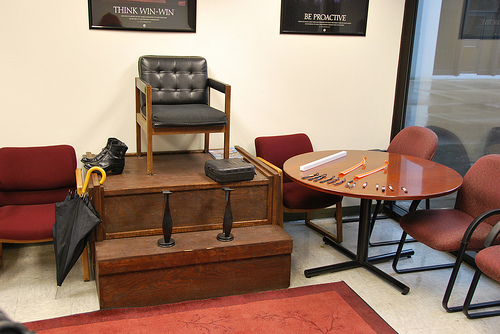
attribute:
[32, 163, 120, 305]
umbrella — black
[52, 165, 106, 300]
umbrella — black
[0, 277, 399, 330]
carpet — red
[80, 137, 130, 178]
boots — red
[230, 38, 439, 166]
wall — white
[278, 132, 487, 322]
tabletop — round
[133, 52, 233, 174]
chair — leather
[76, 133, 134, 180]
boots — black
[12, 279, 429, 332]
carpet — red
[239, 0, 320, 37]
carpet — red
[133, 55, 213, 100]
backrest — black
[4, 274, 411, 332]
carpet — red